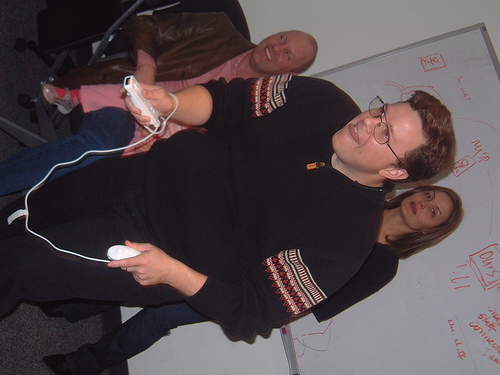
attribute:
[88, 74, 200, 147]
controller — white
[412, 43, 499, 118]
writing — red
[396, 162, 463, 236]
woman — looking, standing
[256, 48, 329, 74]
man — smiling, wearing, sitting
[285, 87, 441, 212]
man — holding, standing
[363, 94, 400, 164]
glasses — black, worn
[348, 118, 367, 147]
tongue — sticking, hanging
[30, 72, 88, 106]
socks — red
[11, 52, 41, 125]
carpet — blue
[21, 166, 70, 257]
cord — white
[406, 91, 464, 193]
hair — short, brown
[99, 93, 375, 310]
sweater — black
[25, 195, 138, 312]
jeans — black, dark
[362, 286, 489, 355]
board — white, hanging, behind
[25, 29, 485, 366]
photo — side view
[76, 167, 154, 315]
pants — black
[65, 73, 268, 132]
child — sitting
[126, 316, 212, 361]
jeans — blue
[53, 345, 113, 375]
shoes — black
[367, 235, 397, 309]
shirt — black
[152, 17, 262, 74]
jacket — brown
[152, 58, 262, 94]
shirt — pink